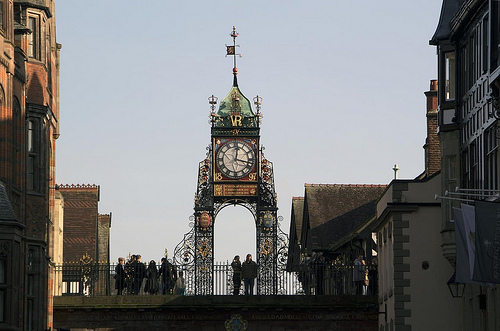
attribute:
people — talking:
[110, 247, 180, 299]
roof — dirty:
[285, 130, 404, 283]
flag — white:
[446, 196, 478, 283]